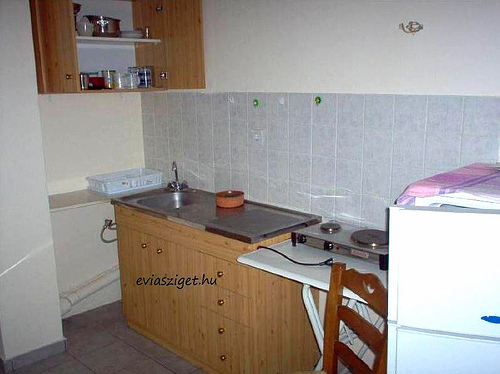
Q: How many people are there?
A: None.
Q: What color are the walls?
A: White.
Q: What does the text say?
A: Eviasziget.hu.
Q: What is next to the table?
A: A fridge.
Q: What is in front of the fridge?
A: A chair.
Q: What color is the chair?
A: Brown.